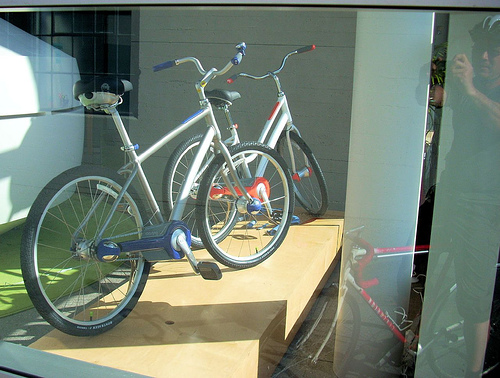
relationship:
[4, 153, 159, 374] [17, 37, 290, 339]
wheel on a bicycle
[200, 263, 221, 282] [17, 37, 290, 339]
paddle on a bicycle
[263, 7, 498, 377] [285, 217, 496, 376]
reflection on bicycle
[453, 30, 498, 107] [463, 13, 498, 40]
head has reflection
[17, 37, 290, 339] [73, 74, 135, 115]
bicycle has seat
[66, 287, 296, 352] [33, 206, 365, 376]
shadow on platform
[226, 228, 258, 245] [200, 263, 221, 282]
shadow on paddle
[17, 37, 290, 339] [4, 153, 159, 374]
bicycle has wheel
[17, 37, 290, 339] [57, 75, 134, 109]
bicycle has seat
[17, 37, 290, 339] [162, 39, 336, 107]
bicycle has handlebars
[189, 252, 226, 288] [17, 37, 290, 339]
paddle on bicycle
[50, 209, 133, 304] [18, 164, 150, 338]
spoke on bike wheel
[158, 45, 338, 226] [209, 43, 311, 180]
bicycle has frame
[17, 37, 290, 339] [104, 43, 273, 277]
bicycle has frame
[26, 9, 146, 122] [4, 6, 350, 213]
window on house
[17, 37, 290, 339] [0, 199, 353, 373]
bicycle on ground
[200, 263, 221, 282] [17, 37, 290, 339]
paddle on bicycle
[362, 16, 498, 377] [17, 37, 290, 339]
man on bicycle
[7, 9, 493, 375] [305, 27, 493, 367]
window has reflection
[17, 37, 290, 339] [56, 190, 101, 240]
bicycle has spoke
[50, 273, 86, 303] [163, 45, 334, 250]
spoke on bicycle bicycle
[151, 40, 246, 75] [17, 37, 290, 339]
handle bars on bicycle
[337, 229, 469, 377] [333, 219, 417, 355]
reflection of bicycle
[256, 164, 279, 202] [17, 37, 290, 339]
spoke on bicycle